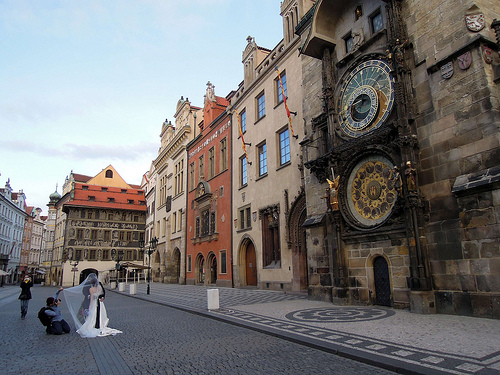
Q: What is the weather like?
A: It is cloudless.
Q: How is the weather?
A: It is cloudless.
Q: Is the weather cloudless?
A: Yes, it is cloudless.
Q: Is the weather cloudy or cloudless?
A: It is cloudless.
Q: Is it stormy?
A: No, it is cloudless.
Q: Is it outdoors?
A: Yes, it is outdoors.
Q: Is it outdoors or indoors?
A: It is outdoors.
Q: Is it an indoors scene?
A: No, it is outdoors.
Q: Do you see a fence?
A: No, there are no fences.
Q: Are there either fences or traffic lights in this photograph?
A: No, there are no fences or traffic lights.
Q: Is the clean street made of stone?
A: Yes, the street is made of stone.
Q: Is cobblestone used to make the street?
A: No, the street is made of stone.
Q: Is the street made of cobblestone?
A: No, the street is made of stone.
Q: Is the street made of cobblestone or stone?
A: The street is made of stone.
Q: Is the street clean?
A: Yes, the street is clean.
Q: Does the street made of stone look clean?
A: Yes, the street is clean.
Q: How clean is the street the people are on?
A: The street is clean.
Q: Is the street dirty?
A: No, the street is clean.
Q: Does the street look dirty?
A: No, the street is clean.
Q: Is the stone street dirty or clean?
A: The street is clean.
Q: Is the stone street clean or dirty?
A: The street is clean.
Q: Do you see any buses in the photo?
A: No, there are no buses.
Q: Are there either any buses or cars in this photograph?
A: No, there are no buses or cars.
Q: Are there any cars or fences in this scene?
A: No, there are no cars or fences.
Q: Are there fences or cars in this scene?
A: No, there are no cars or fences.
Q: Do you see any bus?
A: No, there are no buses.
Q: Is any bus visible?
A: No, there are no buses.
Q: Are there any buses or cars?
A: No, there are no buses or cars.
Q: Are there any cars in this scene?
A: No, there are no cars.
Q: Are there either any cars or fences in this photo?
A: No, there are no cars or fences.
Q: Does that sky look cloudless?
A: Yes, the sky is cloudless.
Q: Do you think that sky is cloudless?
A: Yes, the sky is cloudless.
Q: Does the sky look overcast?
A: No, the sky is cloudless.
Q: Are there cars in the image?
A: No, there are no cars.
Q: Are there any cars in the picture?
A: No, there are no cars.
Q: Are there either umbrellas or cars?
A: No, there are no cars or umbrellas.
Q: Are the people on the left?
A: Yes, the people are on the left of the image.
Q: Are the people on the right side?
A: No, the people are on the left of the image.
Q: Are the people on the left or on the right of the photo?
A: The people are on the left of the image.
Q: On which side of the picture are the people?
A: The people are on the left of the image.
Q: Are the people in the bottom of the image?
A: Yes, the people are in the bottom of the image.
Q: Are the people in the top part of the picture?
A: No, the people are in the bottom of the image.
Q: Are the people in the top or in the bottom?
A: The people are in the bottom of the image.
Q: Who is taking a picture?
A: The people are taking a picture.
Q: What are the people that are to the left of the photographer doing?
A: The people are taking a picture.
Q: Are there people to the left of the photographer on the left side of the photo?
A: Yes, there are people to the left of the photographer.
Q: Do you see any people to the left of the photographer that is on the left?
A: Yes, there are people to the left of the photographer.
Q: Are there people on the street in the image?
A: Yes, there are people on the street.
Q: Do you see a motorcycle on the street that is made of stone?
A: No, there are people on the street.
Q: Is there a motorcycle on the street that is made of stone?
A: No, there are people on the street.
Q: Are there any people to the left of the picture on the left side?
A: Yes, there are people to the left of the picture.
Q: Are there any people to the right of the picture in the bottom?
A: No, the people are to the left of the picture.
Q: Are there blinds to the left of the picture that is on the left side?
A: No, there are people to the left of the picture.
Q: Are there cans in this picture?
A: Yes, there is a can.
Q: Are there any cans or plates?
A: Yes, there is a can.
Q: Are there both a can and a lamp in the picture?
A: Yes, there are both a can and a lamp.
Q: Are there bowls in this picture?
A: No, there are no bowls.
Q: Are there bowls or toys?
A: No, there are no bowls or toys.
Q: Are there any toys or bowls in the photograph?
A: No, there are no bowls or toys.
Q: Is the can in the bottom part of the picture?
A: Yes, the can is in the bottom of the image.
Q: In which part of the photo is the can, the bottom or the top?
A: The can is in the bottom of the image.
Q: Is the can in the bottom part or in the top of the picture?
A: The can is in the bottom of the image.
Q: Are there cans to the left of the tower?
A: Yes, there is a can to the left of the tower.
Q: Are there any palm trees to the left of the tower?
A: No, there is a can to the left of the tower.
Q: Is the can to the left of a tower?
A: Yes, the can is to the left of a tower.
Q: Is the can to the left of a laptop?
A: No, the can is to the left of a tower.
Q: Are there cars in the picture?
A: No, there are no cars.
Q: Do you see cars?
A: No, there are no cars.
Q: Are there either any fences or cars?
A: No, there are no cars or fences.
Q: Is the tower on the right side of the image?
A: Yes, the tower is on the right of the image.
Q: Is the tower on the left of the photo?
A: No, the tower is on the right of the image.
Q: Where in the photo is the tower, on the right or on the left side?
A: The tower is on the right of the image.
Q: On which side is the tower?
A: The tower is on the right of the image.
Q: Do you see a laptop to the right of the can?
A: No, there is a tower to the right of the can.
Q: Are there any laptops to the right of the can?
A: No, there is a tower to the right of the can.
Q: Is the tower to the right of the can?
A: Yes, the tower is to the right of the can.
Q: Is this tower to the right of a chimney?
A: No, the tower is to the right of the can.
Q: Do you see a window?
A: Yes, there are windows.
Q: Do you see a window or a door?
A: Yes, there are windows.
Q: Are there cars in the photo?
A: No, there are no cars.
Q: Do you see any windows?
A: Yes, there is a window.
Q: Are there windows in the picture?
A: Yes, there is a window.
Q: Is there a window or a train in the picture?
A: Yes, there is a window.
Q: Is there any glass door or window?
A: Yes, there is a glass window.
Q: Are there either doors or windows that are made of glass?
A: Yes, the window is made of glass.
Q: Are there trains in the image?
A: No, there are no trains.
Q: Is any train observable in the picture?
A: No, there are no trains.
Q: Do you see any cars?
A: No, there are no cars.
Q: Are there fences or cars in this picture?
A: No, there are no cars or fences.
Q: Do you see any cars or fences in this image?
A: No, there are no cars or fences.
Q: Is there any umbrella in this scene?
A: No, there are no umbrellas.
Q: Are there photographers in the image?
A: Yes, there is a photographer.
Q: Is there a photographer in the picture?
A: Yes, there is a photographer.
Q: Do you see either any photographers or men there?
A: Yes, there is a photographer.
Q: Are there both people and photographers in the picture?
A: Yes, there are both a photographer and a person.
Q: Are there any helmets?
A: No, there are no helmets.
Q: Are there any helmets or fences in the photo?
A: No, there are no helmets or fences.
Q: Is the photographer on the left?
A: Yes, the photographer is on the left of the image.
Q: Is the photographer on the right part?
A: No, the photographer is on the left of the image.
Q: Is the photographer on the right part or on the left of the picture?
A: The photographer is on the left of the image.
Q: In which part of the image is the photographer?
A: The photographer is on the left of the image.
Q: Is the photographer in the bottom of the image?
A: Yes, the photographer is in the bottom of the image.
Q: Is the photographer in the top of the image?
A: No, the photographer is in the bottom of the image.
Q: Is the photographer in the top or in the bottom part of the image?
A: The photographer is in the bottom of the image.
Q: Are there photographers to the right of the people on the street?
A: Yes, there is a photographer to the right of the people.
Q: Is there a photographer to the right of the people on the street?
A: Yes, there is a photographer to the right of the people.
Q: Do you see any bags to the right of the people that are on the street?
A: No, there is a photographer to the right of the people.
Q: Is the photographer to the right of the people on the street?
A: Yes, the photographer is to the right of the people.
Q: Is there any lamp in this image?
A: Yes, there is a lamp.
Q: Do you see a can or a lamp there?
A: Yes, there is a lamp.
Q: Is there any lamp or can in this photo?
A: Yes, there is a lamp.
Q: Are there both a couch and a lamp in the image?
A: No, there is a lamp but no couches.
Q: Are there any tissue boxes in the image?
A: No, there are no tissue boxes.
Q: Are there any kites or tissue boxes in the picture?
A: No, there are no tissue boxes or kites.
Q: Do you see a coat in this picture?
A: Yes, there is a coat.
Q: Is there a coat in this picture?
A: Yes, there is a coat.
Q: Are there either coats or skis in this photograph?
A: Yes, there is a coat.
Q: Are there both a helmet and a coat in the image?
A: No, there is a coat but no helmets.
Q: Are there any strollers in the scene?
A: No, there are no strollers.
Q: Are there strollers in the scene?
A: No, there are no strollers.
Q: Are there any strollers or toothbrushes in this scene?
A: No, there are no strollers or toothbrushes.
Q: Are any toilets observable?
A: No, there are no toilets.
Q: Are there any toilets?
A: No, there are no toilets.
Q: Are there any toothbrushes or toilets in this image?
A: No, there are no toilets or toothbrushes.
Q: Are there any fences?
A: No, there are no fences.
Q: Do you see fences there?
A: No, there are no fences.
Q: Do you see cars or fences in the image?
A: No, there are no fences or cars.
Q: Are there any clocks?
A: Yes, there is a clock.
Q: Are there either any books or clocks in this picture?
A: Yes, there is a clock.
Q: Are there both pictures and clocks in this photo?
A: Yes, there are both a clock and a picture.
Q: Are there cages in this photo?
A: No, there are no cages.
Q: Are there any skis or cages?
A: No, there are no cages or skis.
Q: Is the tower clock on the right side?
A: Yes, the clock is on the right of the image.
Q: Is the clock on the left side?
A: No, the clock is on the right of the image.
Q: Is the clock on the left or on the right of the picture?
A: The clock is on the right of the image.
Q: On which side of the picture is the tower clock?
A: The clock is on the right of the image.